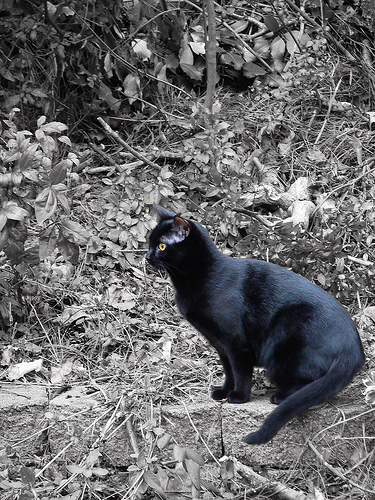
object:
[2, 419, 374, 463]
wall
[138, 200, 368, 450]
cat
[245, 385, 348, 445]
tail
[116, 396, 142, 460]
branches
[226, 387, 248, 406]
paw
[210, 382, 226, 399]
paw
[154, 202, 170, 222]
ear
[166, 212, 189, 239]
ear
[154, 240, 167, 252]
eye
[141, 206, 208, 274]
head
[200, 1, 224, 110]
trunk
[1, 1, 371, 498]
photo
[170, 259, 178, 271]
whiskers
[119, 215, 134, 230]
leaves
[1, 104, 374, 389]
ground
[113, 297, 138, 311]
leaves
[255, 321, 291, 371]
stomach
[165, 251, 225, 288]
neck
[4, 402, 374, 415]
edge